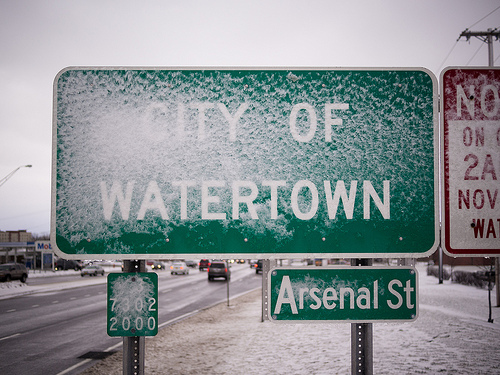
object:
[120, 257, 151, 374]
pole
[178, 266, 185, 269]
tail light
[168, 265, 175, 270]
tail light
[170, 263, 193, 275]
car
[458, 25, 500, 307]
electric pole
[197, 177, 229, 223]
letter e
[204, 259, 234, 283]
car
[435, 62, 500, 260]
sign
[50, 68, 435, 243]
snow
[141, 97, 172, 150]
letter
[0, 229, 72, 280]
gas station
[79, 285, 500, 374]
snow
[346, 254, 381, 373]
post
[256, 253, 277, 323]
pole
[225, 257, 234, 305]
pole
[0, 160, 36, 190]
light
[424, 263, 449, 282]
bush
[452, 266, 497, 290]
bush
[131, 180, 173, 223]
letter a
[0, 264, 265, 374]
road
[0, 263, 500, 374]
ground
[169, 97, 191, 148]
letter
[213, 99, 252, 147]
letter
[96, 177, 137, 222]
letter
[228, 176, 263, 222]
letter r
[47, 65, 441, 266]
sign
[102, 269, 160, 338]
sign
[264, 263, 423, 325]
sign